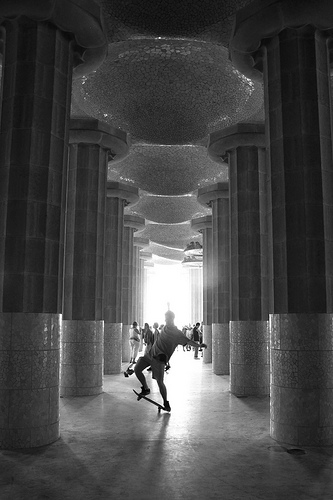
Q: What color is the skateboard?
A: Black.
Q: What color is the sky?
A: White.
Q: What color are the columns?
A: Gray.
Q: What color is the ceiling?
A: Gray.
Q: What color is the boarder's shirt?
A: Gray.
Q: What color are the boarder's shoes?
A: Black.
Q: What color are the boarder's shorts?
A: Gray.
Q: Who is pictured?
A: A skateboarder.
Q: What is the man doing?
A: Skateboarding.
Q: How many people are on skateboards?
A: Just 1.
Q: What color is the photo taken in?
A: Black and white.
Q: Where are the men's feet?
A: Planted on the skateboard.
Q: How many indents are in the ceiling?
A: 7.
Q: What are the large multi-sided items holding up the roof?
A: Pillars.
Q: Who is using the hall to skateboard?
A: A man in knee-length shorts.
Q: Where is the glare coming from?
A: Sunlight, at the far end of the hall.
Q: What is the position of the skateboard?
A: It is tilted upwards, to the left.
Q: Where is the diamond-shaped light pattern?
A: On the floor.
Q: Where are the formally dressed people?
A: There are none.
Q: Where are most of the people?
A: At the far end of the hall.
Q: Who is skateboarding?
A: The man.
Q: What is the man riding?
A: A skateboarding.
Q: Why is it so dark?
A: The man is inside.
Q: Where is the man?
A: Inside the building.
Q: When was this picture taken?
A: During the day.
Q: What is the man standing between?
A: Columns.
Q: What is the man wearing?
A: Shorts.